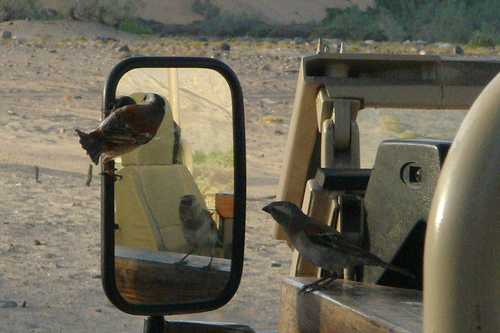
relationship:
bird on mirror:
[261, 197, 418, 297] [100, 51, 252, 326]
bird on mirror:
[72, 92, 164, 182] [95, 58, 260, 315]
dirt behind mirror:
[5, 190, 90, 329] [100, 51, 252, 326]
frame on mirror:
[99, 53, 246, 317] [109, 59, 243, 304]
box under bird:
[275, 275, 427, 331] [261, 197, 418, 297]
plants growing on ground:
[9, 32, 499, 53] [1, 21, 497, 332]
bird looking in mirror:
[72, 89, 170, 174] [100, 51, 252, 326]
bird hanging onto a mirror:
[72, 92, 164, 182] [115, 33, 237, 320]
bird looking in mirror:
[72, 92, 164, 182] [100, 51, 252, 326]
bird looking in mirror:
[261, 197, 418, 297] [100, 51, 252, 326]